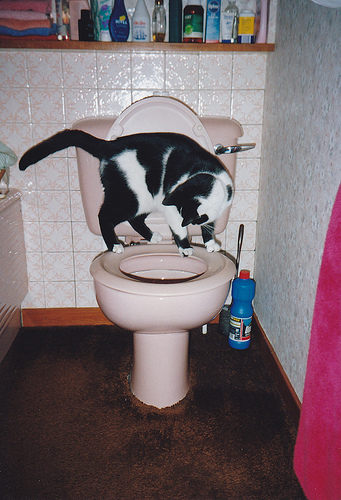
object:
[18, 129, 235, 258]
cat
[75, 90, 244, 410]
toilet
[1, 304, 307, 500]
floor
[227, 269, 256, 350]
bottle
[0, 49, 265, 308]
tiles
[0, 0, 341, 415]
wall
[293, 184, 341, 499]
towel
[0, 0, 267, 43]
stuff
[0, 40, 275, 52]
shelf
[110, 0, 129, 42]
bottle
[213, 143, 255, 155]
handle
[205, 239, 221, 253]
paw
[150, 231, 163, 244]
paw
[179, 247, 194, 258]
paw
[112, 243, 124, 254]
paw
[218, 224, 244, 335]
toilet brush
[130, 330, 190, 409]
baseboard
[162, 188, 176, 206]
ear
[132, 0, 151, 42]
bottle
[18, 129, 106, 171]
tail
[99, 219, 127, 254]
legs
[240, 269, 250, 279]
cap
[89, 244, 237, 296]
toilet seat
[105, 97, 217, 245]
cover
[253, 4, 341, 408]
wallpaper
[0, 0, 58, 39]
towels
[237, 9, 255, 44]
powder bottle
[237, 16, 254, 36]
label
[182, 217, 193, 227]
ears